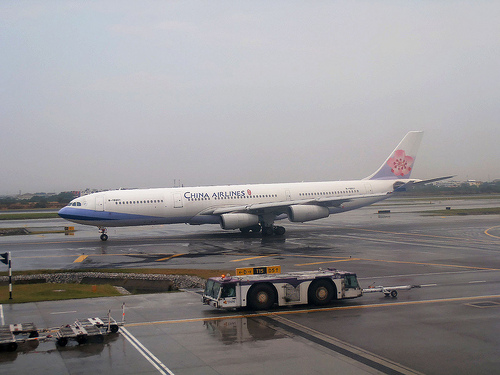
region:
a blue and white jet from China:
[56, 128, 460, 239]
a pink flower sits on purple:
[373, 149, 416, 178]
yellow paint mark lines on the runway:
[28, 246, 390, 271]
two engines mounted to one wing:
[218, 204, 346, 225]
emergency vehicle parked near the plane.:
[202, 263, 363, 312]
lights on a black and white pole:
[0, 248, 17, 301]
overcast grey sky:
[1, 0, 494, 192]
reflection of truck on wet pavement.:
[207, 309, 306, 357]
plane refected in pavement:
[162, 228, 356, 261]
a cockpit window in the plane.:
[53, 192, 93, 220]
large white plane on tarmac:
[56, 133, 449, 251]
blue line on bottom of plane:
[63, 208, 150, 225]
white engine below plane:
[205, 208, 265, 227]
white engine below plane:
[287, 199, 329, 221]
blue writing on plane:
[172, 182, 249, 199]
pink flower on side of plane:
[378, 131, 427, 178]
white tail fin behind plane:
[375, 127, 429, 184]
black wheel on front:
[96, 233, 116, 243]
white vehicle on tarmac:
[192, 257, 447, 312]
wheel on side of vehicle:
[253, 280, 278, 304]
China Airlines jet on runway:
[53, 122, 470, 254]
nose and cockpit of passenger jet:
[54, 181, 104, 222]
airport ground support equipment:
[200, 262, 388, 323]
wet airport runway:
[30, 241, 490, 265]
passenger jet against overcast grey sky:
[19, 14, 462, 245]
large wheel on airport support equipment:
[247, 281, 282, 318]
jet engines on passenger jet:
[203, 197, 348, 232]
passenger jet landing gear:
[81, 221, 121, 251]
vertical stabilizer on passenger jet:
[355, 115, 429, 190]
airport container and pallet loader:
[13, 305, 142, 354]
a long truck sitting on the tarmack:
[198, 272, 370, 307]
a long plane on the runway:
[50, 130, 452, 232]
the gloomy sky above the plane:
[0, 5, 495, 185]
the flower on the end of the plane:
[383, 148, 412, 176]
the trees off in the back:
[448, 178, 499, 197]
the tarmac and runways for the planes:
[6, 217, 492, 372]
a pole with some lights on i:
[0, 248, 16, 299]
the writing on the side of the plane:
[181, 187, 250, 201]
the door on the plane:
[89, 197, 106, 214]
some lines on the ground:
[73, 250, 338, 275]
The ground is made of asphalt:
[426, 230, 488, 370]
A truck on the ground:
[193, 250, 430, 316]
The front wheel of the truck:
[241, 277, 280, 314]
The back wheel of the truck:
[303, 276, 339, 308]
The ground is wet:
[129, 308, 359, 371]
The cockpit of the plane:
[63, 195, 89, 210]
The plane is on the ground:
[55, 119, 461, 247]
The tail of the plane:
[367, 118, 426, 180]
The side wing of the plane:
[213, 180, 397, 234]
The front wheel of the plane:
[92, 223, 112, 245]